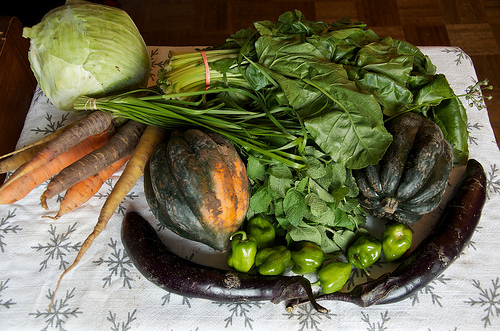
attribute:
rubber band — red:
[200, 50, 212, 90]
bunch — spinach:
[157, 11, 469, 166]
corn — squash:
[140, 117, 257, 252]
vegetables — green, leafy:
[19, 2, 474, 299]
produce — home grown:
[2, 1, 492, 308]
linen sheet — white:
[1, 49, 498, 329]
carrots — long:
[32, 134, 177, 242]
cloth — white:
[29, 243, 173, 328]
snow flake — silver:
[27, 286, 82, 329]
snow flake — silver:
[209, 297, 266, 329]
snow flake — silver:
[462, 274, 498, 327]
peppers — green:
[221, 216, 416, 297]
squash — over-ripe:
[136, 125, 255, 256]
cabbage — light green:
[23, 2, 153, 110]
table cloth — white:
[0, 45, 498, 329]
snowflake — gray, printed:
[32, 221, 79, 273]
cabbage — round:
[8, 2, 150, 111]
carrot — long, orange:
[118, 153, 146, 198]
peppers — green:
[229, 224, 419, 296]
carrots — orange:
[2, 102, 164, 300]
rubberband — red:
[193, 46, 213, 93]